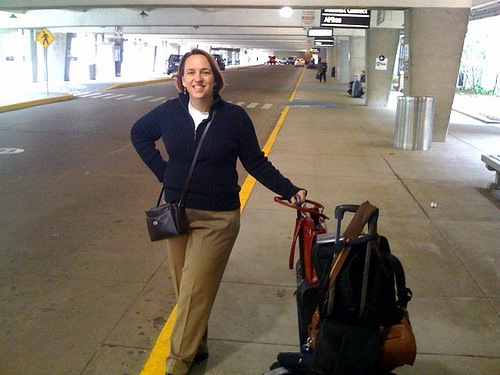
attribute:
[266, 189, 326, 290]
handle — red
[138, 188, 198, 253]
purse — leather, cross-body, brown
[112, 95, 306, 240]
sweater — black, zip-up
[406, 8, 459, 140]
pillar — large, concrete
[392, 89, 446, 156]
trash can — silver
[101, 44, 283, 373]
woman — cross legged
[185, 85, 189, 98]
earring — down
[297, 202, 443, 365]
suitcase — black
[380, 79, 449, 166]
trash can — silver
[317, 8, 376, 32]
sign — lit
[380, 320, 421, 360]
bag — brown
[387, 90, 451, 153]
dustbin — steel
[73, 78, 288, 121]
pedestrain walk — white